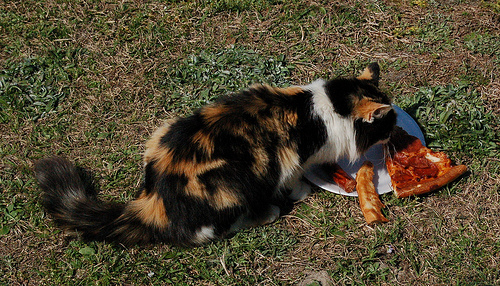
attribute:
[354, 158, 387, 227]
pizza crust — brown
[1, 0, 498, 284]
grass — dry, short, brown, green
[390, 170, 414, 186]
pepperoni — red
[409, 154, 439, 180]
pepperoni — red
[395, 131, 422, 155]
pepperoni — red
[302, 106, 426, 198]
plate — white, round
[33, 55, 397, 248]
cat — black, brown, eating, calico, orange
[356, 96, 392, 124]
ear — orange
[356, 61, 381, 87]
ear — orange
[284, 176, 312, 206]
paw — white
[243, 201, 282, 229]
paw — white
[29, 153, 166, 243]
tail — black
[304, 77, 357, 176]
neck — white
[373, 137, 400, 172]
whiskers — white